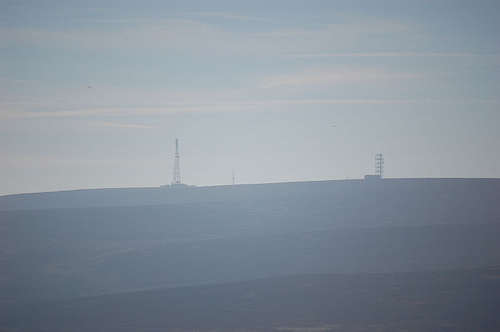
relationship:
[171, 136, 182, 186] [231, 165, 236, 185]
tower to left of structure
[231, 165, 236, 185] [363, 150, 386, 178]
structure to left of structure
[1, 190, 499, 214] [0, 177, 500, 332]
ripple visible in ground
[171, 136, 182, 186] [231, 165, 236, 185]
tower taller than structure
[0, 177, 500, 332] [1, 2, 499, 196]
ground beneath sky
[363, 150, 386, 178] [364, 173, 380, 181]
structure next to building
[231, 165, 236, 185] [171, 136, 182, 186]
structure to right of tower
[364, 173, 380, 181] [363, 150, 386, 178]
building near structure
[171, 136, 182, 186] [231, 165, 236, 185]
tower standing above structure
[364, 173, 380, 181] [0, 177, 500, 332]
building overlooking ground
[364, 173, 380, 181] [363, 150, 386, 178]
building at base of structure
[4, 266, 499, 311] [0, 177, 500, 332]
ridge in ground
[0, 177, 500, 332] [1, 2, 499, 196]
ground meets sky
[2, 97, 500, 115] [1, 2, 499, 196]
cloud floating in sky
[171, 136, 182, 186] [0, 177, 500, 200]
tower on horizon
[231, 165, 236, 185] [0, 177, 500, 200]
structure on horizon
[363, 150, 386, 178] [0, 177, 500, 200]
structure on horizon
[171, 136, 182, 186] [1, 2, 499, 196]
tower below sky